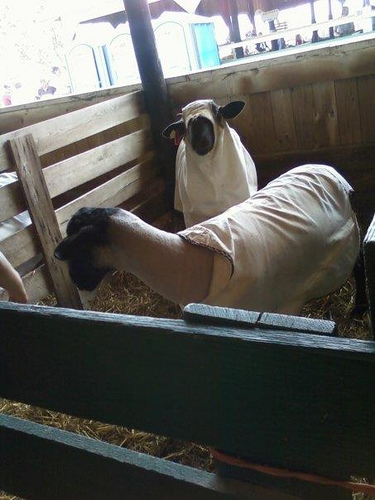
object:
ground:
[361, 214, 370, 226]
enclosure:
[2, 35, 372, 499]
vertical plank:
[259, 309, 337, 339]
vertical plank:
[182, 302, 262, 324]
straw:
[0, 398, 213, 472]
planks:
[0, 301, 373, 483]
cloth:
[181, 159, 231, 202]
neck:
[119, 206, 211, 304]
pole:
[123, 0, 177, 206]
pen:
[0, 24, 373, 498]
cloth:
[236, 274, 278, 306]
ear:
[218, 96, 245, 119]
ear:
[162, 119, 186, 139]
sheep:
[162, 93, 257, 228]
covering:
[179, 163, 361, 313]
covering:
[173, 99, 257, 228]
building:
[58, 0, 374, 63]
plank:
[264, 89, 302, 146]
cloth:
[261, 221, 324, 262]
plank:
[0, 415, 266, 498]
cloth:
[187, 102, 208, 112]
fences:
[4, 36, 375, 500]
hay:
[92, 284, 140, 306]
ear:
[54, 225, 94, 261]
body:
[54, 162, 370, 316]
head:
[162, 99, 246, 156]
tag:
[170, 131, 175, 138]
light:
[0, 411, 229, 500]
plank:
[247, 83, 276, 138]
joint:
[249, 311, 268, 340]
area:
[0, 0, 374, 498]